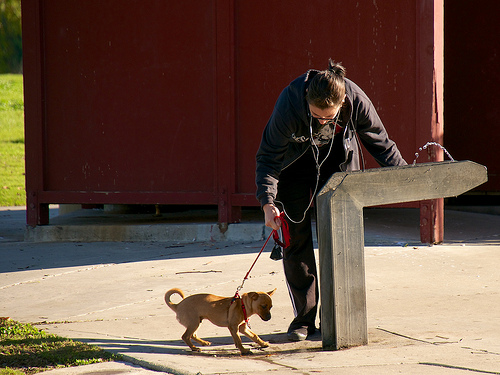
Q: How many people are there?
A: One.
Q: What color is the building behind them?
A: Red.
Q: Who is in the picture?
A: A woman and a dog.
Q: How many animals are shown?
A: One.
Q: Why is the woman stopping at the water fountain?
A: To get a drink.